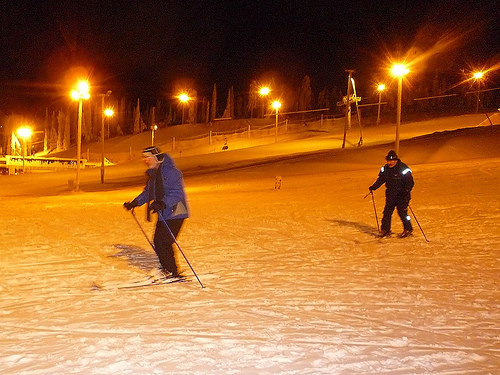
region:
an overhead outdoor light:
[13, 121, 31, 159]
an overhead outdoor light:
[68, 75, 87, 158]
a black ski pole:
[150, 206, 205, 290]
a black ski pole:
[125, 205, 151, 250]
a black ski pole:
[405, 194, 430, 244]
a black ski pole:
[362, 185, 382, 233]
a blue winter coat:
[131, 156, 188, 221]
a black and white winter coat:
[372, 161, 415, 200]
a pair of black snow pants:
[380, 197, 412, 236]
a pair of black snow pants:
[149, 215, 182, 275]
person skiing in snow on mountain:
[116, 142, 191, 302]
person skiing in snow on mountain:
[360, 146, 424, 256]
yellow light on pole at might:
[59, 76, 96, 107]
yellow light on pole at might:
[6, 126, 41, 144]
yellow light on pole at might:
[93, 99, 123, 129]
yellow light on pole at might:
[172, 91, 214, 118]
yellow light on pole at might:
[259, 85, 276, 122]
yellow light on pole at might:
[275, 91, 285, 132]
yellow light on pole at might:
[379, 46, 417, 96]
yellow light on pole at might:
[469, 58, 487, 106]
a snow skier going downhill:
[112, 145, 214, 293]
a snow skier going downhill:
[355, 149, 436, 243]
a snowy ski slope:
[2, 105, 495, 372]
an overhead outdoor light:
[385, 54, 410, 151]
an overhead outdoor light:
[465, 65, 483, 109]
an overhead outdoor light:
[371, 79, 386, 121]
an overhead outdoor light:
[264, 94, 286, 137]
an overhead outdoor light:
[256, 81, 271, 116]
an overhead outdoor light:
[175, 89, 189, 123]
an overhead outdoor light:
[102, 103, 116, 138]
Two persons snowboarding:
[103, 123, 458, 325]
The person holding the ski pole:
[123, 205, 208, 291]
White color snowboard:
[91, 273, 226, 288]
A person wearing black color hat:
[381, 150, 403, 163]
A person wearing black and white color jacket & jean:
[348, 160, 435, 248]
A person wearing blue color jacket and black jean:
[105, 141, 240, 306]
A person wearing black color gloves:
[118, 197, 163, 214]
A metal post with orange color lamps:
[11, 43, 488, 170]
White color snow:
[126, 305, 384, 342]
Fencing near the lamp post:
[171, 122, 303, 149]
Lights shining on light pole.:
[68, 74, 90, 187]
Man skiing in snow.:
[364, 153, 433, 252]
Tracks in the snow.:
[72, 312, 298, 374]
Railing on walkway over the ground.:
[5, 150, 91, 176]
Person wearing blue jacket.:
[126, 145, 212, 297]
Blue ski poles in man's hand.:
[147, 199, 211, 290]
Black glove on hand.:
[144, 191, 173, 233]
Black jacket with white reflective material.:
[367, 149, 428, 246]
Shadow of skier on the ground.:
[326, 204, 381, 242]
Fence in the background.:
[360, 93, 482, 124]